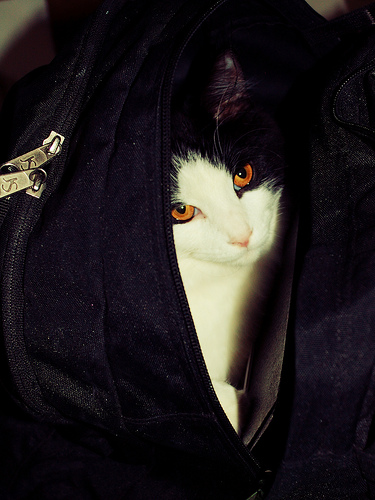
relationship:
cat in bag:
[165, 51, 288, 437] [0, 0, 373, 498]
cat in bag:
[165, 51, 288, 437] [33, 93, 166, 410]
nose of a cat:
[216, 220, 262, 255] [139, 124, 319, 373]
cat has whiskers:
[165, 51, 288, 437] [178, 185, 282, 269]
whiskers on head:
[178, 185, 282, 269] [169, 49, 285, 272]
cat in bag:
[165, 48, 288, 433] [19, 2, 349, 467]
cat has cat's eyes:
[165, 51, 288, 437] [169, 157, 252, 223]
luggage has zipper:
[1, 0, 373, 497] [5, 170, 53, 197]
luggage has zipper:
[1, 0, 373, 497] [6, 131, 78, 167]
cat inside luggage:
[165, 48, 288, 433] [1, 0, 373, 497]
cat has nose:
[165, 51, 288, 437] [226, 226, 252, 249]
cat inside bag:
[165, 51, 288, 437] [0, 0, 375, 499]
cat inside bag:
[165, 48, 288, 433] [32, 28, 372, 313]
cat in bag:
[165, 48, 288, 433] [9, 43, 373, 494]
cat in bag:
[165, 48, 288, 433] [0, 0, 373, 498]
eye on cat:
[168, 201, 197, 223] [156, 82, 288, 428]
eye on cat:
[231, 161, 259, 191] [174, 24, 302, 444]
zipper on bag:
[4, 127, 65, 199] [0, 0, 375, 499]